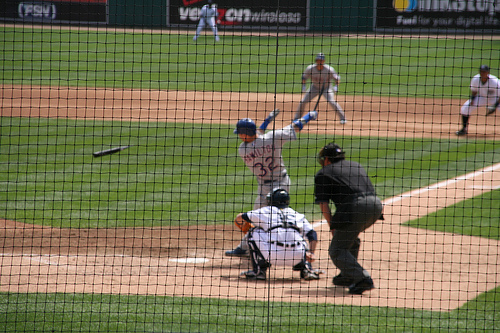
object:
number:
[251, 156, 278, 177]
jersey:
[238, 124, 295, 186]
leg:
[324, 89, 347, 118]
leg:
[292, 89, 311, 117]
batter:
[234, 109, 318, 210]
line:
[380, 150, 500, 204]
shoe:
[331, 269, 352, 286]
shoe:
[346, 274, 372, 294]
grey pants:
[255, 173, 288, 207]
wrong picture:
[96, 61, 444, 284]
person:
[296, 53, 347, 126]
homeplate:
[174, 256, 212, 265]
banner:
[166, 0, 311, 31]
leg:
[301, 252, 313, 271]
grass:
[401, 186, 498, 243]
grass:
[4, 28, 498, 99]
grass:
[4, 116, 500, 228]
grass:
[4, 282, 500, 333]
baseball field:
[0, 0, 499, 333]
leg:
[329, 209, 367, 279]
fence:
[1, 0, 500, 333]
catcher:
[234, 187, 319, 280]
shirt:
[241, 206, 310, 246]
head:
[234, 118, 256, 143]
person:
[455, 65, 500, 135]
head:
[268, 187, 290, 206]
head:
[312, 55, 326, 67]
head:
[479, 66, 491, 79]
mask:
[265, 187, 283, 202]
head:
[317, 142, 346, 163]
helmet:
[268, 187, 289, 208]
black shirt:
[311, 157, 377, 202]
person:
[307, 142, 389, 295]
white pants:
[244, 229, 307, 268]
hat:
[233, 118, 255, 136]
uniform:
[291, 62, 346, 121]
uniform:
[232, 125, 294, 250]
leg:
[457, 97, 472, 127]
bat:
[91, 146, 127, 158]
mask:
[317, 150, 327, 165]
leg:
[251, 183, 268, 207]